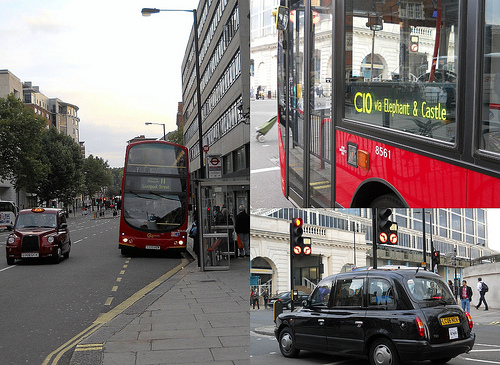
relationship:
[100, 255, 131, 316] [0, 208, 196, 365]
lines on city street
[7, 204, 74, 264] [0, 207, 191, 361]
taxi on city street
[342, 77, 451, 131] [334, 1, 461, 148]
sign on window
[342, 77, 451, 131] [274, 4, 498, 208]
sign on bus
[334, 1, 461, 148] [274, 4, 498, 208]
window on bus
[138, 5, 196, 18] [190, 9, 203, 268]
street light on pole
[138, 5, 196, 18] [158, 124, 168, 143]
street light on pole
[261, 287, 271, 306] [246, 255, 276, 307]
person standing under archway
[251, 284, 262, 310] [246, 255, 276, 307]
person standing under archway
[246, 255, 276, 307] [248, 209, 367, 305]
archway of building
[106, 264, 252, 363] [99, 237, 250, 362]
pattern on sidewalk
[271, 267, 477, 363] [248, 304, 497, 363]
cab on street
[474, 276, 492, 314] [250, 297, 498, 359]
man walks down street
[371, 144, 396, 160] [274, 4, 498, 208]
number on bus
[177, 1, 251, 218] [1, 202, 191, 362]
building on street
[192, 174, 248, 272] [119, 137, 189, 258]
waiting station next to bus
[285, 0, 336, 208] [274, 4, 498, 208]
door of bus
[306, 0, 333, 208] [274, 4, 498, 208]
door of bus